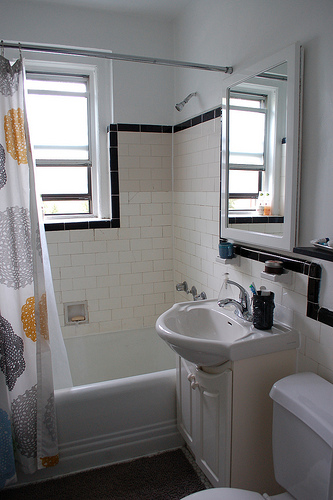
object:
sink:
[153, 297, 292, 360]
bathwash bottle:
[263, 190, 273, 217]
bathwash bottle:
[255, 191, 265, 215]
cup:
[219, 241, 234, 258]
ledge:
[214, 254, 241, 266]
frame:
[219, 45, 298, 252]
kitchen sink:
[155, 276, 292, 368]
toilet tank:
[268, 369, 333, 498]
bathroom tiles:
[128, 143, 152, 156]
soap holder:
[70, 313, 86, 324]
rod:
[0, 41, 234, 75]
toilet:
[175, 371, 332, 500]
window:
[0, 45, 112, 224]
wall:
[1, 4, 173, 340]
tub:
[53, 324, 185, 475]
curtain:
[1, 35, 67, 489]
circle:
[4, 107, 32, 165]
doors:
[173, 356, 238, 490]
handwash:
[154, 297, 256, 344]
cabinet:
[175, 352, 275, 487]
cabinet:
[220, 40, 305, 252]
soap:
[68, 312, 89, 322]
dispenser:
[64, 299, 90, 325]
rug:
[84, 469, 183, 496]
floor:
[0, 447, 206, 500]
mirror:
[224, 59, 287, 238]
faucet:
[217, 276, 251, 319]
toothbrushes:
[249, 281, 256, 296]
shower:
[174, 86, 200, 118]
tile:
[95, 251, 121, 264]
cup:
[252, 286, 276, 331]